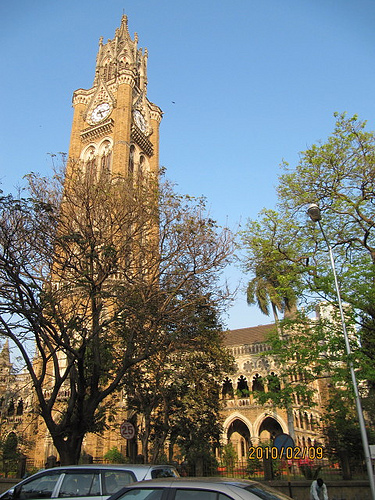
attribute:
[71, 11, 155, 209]
tower — brown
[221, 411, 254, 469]
arches — large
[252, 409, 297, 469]
arches — large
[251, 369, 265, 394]
arches — large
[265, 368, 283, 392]
arches — large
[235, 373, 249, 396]
arches — large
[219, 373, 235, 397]
arches — large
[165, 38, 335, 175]
clouds — white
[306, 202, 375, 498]
street lamp — tall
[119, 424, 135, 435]
number 25 — red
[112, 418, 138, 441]
sign — red, white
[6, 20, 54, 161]
clouds — white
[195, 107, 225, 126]
clouds — white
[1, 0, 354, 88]
sky — blue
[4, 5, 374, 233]
sky — blue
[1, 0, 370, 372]
sky — blue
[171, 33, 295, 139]
sky — blue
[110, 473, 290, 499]
car — silver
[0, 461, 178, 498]
car — silver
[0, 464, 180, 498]
hatchback — silver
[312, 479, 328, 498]
shirt — silver